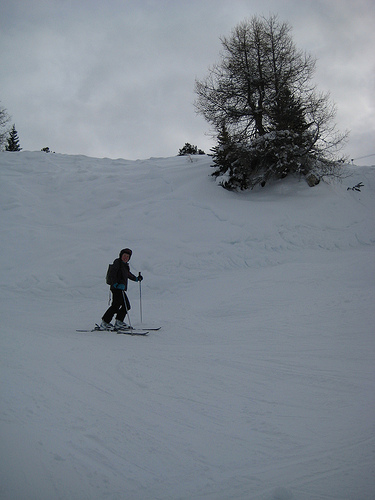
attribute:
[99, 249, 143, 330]
skiier — here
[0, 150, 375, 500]
snow — here, white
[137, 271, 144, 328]
pole — here, metal, long, black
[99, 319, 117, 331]
boots — white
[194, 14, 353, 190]
tree — dead, bare, present, here, green, large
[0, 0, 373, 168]
sky — gray, cloudy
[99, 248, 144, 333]
boy — skiing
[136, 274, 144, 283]
glove — blue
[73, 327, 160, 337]
ski — black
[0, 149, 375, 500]
hill — large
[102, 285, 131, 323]
pants — black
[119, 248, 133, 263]
hat — black